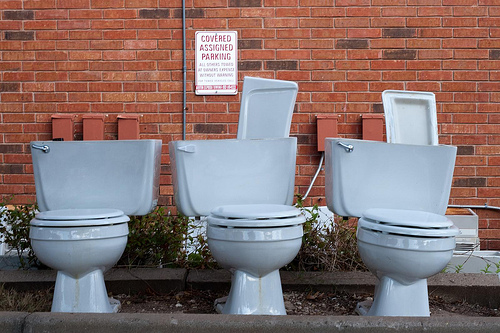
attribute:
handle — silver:
[31, 140, 51, 155]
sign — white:
[186, 24, 253, 114]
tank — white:
[321, 134, 462, 218]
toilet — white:
[19, 123, 162, 289]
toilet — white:
[172, 121, 324, 272]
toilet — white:
[330, 119, 498, 284]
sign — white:
[187, 28, 239, 98]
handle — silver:
[331, 127, 356, 161]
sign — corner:
[191, 27, 239, 95]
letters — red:
[199, 32, 206, 44]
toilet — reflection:
[184, 139, 295, 306]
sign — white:
[193, 29, 240, 96]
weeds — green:
[2, 201, 498, 277]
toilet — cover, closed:
[202, 201, 314, 276]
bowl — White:
[386, 187, 433, 294]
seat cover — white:
[211, 187, 299, 226]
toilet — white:
[325, 79, 499, 331]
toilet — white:
[175, 68, 310, 321]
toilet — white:
[2, 81, 169, 323]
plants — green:
[145, 213, 194, 257]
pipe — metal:
[447, 200, 499, 212]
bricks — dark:
[331, 23, 425, 76]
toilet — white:
[322, 131, 464, 321]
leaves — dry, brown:
[148, 235, 176, 259]